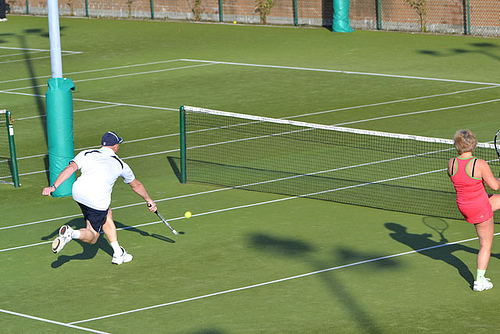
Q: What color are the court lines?
A: White.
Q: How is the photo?
A: Clear.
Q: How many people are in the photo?
A: Two.